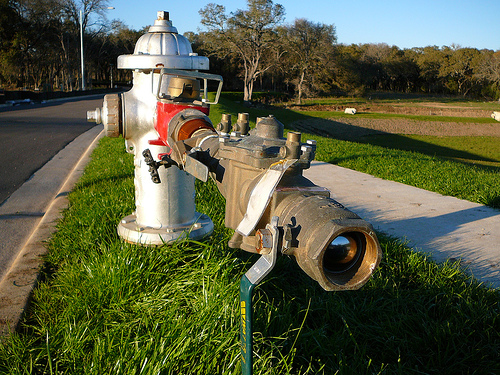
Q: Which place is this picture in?
A: It is at the field.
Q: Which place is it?
A: It is a field.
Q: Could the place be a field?
A: Yes, it is a field.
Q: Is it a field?
A: Yes, it is a field.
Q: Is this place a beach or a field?
A: It is a field.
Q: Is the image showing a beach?
A: No, the picture is showing a field.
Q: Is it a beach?
A: No, it is a field.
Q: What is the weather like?
A: It is clear.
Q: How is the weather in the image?
A: It is clear.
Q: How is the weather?
A: It is clear.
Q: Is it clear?
A: Yes, it is clear.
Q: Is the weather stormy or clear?
A: It is clear.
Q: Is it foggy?
A: No, it is clear.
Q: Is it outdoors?
A: Yes, it is outdoors.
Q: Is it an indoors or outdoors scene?
A: It is outdoors.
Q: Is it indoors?
A: No, it is outdoors.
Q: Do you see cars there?
A: No, there are no cars.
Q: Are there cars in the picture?
A: No, there are no cars.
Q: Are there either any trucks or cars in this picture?
A: No, there are no cars or trucks.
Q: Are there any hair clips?
A: No, there are no hair clips.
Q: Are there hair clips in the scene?
A: No, there are no hair clips.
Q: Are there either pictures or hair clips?
A: No, there are no hair clips or pictures.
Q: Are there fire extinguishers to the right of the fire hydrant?
A: Yes, there is a fire extinguisher to the right of the fire hydrant.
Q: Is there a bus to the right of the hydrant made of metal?
A: No, there is a fire extinguisher to the right of the hydrant.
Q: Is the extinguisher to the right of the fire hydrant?
A: Yes, the extinguisher is to the right of the fire hydrant.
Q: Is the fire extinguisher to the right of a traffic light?
A: No, the fire extinguisher is to the right of the fire hydrant.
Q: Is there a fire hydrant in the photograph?
A: Yes, there is a fire hydrant.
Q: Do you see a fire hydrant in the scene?
A: Yes, there is a fire hydrant.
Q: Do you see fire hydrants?
A: Yes, there is a fire hydrant.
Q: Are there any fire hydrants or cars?
A: Yes, there is a fire hydrant.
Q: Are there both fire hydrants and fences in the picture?
A: No, there is a fire hydrant but no fences.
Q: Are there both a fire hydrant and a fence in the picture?
A: No, there is a fire hydrant but no fences.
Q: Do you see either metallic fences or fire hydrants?
A: Yes, there is a metal fire hydrant.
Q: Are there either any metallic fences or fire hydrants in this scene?
A: Yes, there is a metal fire hydrant.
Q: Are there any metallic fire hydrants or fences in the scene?
A: Yes, there is a metal fire hydrant.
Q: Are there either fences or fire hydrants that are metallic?
A: Yes, the fire hydrant is metallic.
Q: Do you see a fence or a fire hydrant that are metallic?
A: Yes, the fire hydrant is metallic.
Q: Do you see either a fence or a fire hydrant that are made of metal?
A: Yes, the fire hydrant is made of metal.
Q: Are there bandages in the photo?
A: No, there are no bandages.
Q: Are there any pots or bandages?
A: No, there are no bandages or pots.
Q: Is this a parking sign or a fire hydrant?
A: This is a fire hydrant.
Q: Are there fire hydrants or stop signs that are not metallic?
A: No, there is a fire hydrant but it is metallic.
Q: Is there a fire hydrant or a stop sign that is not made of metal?
A: No, there is a fire hydrant but it is made of metal.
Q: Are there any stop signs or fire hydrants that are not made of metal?
A: No, there is a fire hydrant but it is made of metal.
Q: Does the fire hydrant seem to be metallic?
A: Yes, the fire hydrant is metallic.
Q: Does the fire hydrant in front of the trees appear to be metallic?
A: Yes, the fire hydrant is metallic.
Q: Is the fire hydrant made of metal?
A: Yes, the fire hydrant is made of metal.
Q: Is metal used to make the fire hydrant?
A: Yes, the fire hydrant is made of metal.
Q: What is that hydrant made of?
A: The hydrant is made of metal.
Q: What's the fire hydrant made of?
A: The hydrant is made of metal.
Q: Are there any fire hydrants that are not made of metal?
A: No, there is a fire hydrant but it is made of metal.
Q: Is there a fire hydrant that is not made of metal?
A: No, there is a fire hydrant but it is made of metal.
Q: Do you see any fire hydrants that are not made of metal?
A: No, there is a fire hydrant but it is made of metal.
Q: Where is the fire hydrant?
A: The fire hydrant is in the grass.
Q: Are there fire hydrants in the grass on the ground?
A: Yes, there is a fire hydrant in the grass.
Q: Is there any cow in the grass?
A: No, there is a fire hydrant in the grass.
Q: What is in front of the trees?
A: The hydrant is in front of the trees.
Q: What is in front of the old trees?
A: The hydrant is in front of the trees.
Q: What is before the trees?
A: The hydrant is in front of the trees.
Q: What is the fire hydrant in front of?
A: The fire hydrant is in front of the trees.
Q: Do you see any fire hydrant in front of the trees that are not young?
A: Yes, there is a fire hydrant in front of the trees.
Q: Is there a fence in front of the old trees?
A: No, there is a fire hydrant in front of the trees.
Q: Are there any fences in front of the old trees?
A: No, there is a fire hydrant in front of the trees.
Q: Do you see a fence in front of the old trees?
A: No, there is a fire hydrant in front of the trees.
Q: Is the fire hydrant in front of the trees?
A: Yes, the fire hydrant is in front of the trees.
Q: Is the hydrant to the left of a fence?
A: No, the hydrant is to the left of the extinguisher.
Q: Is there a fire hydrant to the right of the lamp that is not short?
A: Yes, there is a fire hydrant to the right of the lamp.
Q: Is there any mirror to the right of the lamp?
A: No, there is a fire hydrant to the right of the lamp.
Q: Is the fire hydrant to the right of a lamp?
A: Yes, the fire hydrant is to the right of a lamp.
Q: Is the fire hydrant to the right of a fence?
A: No, the fire hydrant is to the right of a lamp.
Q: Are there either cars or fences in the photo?
A: No, there are no fences or cars.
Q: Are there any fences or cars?
A: No, there are no fences or cars.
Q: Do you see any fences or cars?
A: No, there are no fences or cars.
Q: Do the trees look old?
A: Yes, the trees are old.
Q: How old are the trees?
A: The trees are old.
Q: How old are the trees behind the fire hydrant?
A: The trees are old.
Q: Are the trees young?
A: No, the trees are old.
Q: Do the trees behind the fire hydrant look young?
A: No, the trees are old.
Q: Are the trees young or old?
A: The trees are old.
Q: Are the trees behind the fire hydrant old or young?
A: The trees are old.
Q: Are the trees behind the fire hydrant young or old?
A: The trees are old.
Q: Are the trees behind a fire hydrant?
A: Yes, the trees are behind a fire hydrant.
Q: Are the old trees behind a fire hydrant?
A: Yes, the trees are behind a fire hydrant.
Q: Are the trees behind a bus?
A: No, the trees are behind a fire hydrant.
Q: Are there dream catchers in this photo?
A: No, there are no dream catchers.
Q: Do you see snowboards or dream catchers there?
A: No, there are no dream catchers or snowboards.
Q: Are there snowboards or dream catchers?
A: No, there are no dream catchers or snowboards.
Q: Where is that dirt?
A: The dirt is in the grass.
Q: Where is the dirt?
A: The dirt is in the grass.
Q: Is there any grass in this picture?
A: Yes, there is grass.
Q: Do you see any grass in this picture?
A: Yes, there is grass.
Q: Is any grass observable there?
A: Yes, there is grass.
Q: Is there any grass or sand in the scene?
A: Yes, there is grass.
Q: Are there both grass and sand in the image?
A: No, there is grass but no sand.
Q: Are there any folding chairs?
A: No, there are no folding chairs.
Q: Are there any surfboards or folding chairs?
A: No, there are no folding chairs or surfboards.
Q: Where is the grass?
A: The grass is on the ground.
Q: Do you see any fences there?
A: No, there are no fences.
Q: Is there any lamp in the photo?
A: Yes, there is a lamp.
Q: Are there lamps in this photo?
A: Yes, there is a lamp.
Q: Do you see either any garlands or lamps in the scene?
A: Yes, there is a lamp.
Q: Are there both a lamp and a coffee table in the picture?
A: No, there is a lamp but no coffee tables.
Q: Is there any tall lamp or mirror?
A: Yes, there is a tall lamp.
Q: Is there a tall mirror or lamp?
A: Yes, there is a tall lamp.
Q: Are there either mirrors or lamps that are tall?
A: Yes, the lamp is tall.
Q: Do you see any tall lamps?
A: Yes, there is a tall lamp.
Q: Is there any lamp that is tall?
A: Yes, there is a lamp that is tall.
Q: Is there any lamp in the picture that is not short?
A: Yes, there is a tall lamp.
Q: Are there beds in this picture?
A: No, there are no beds.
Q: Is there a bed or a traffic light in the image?
A: No, there are no beds or traffic lights.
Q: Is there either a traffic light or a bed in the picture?
A: No, there are no beds or traffic lights.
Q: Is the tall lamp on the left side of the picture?
A: Yes, the lamp is on the left of the image.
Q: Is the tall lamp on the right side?
A: No, the lamp is on the left of the image.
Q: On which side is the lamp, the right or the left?
A: The lamp is on the left of the image.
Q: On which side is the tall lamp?
A: The lamp is on the left of the image.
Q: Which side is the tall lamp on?
A: The lamp is on the left of the image.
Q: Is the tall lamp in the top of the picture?
A: Yes, the lamp is in the top of the image.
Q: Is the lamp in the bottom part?
A: No, the lamp is in the top of the image.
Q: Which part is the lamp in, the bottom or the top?
A: The lamp is in the top of the image.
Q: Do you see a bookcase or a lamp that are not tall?
A: No, there is a lamp but it is tall.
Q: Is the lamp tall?
A: Yes, the lamp is tall.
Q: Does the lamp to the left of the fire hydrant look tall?
A: Yes, the lamp is tall.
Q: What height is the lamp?
A: The lamp is tall.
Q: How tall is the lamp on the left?
A: The lamp is tall.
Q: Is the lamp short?
A: No, the lamp is tall.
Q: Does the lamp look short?
A: No, the lamp is tall.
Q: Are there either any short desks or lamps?
A: No, there is a lamp but it is tall.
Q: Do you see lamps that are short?
A: No, there is a lamp but it is tall.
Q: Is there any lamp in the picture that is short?
A: No, there is a lamp but it is tall.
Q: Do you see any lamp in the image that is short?
A: No, there is a lamp but it is tall.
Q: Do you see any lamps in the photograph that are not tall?
A: No, there is a lamp but it is tall.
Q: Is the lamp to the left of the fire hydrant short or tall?
A: The lamp is tall.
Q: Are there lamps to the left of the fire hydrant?
A: Yes, there is a lamp to the left of the fire hydrant.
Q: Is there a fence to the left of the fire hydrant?
A: No, there is a lamp to the left of the fire hydrant.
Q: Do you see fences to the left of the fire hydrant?
A: No, there is a lamp to the left of the fire hydrant.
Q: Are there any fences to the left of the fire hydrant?
A: No, there is a lamp to the left of the fire hydrant.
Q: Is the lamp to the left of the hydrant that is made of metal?
A: Yes, the lamp is to the left of the fire hydrant.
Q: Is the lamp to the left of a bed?
A: No, the lamp is to the left of the fire hydrant.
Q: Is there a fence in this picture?
A: No, there are no fences.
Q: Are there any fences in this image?
A: No, there are no fences.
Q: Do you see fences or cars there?
A: No, there are no fences or cars.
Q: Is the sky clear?
A: Yes, the sky is clear.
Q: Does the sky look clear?
A: Yes, the sky is clear.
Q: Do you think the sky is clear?
A: Yes, the sky is clear.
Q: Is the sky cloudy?
A: No, the sky is clear.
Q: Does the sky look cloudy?
A: No, the sky is clear.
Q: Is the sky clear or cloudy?
A: The sky is clear.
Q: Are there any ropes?
A: No, there are no ropes.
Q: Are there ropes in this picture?
A: No, there are no ropes.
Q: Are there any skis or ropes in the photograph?
A: No, there are no ropes or skis.